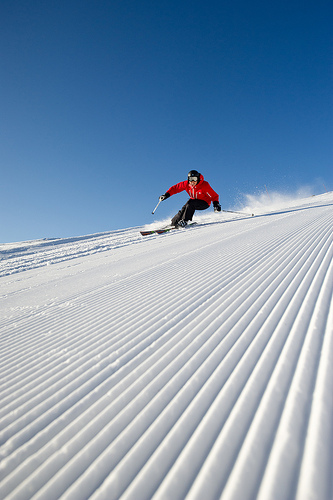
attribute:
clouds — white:
[235, 46, 293, 81]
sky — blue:
[2, 3, 329, 167]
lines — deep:
[2, 248, 317, 496]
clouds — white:
[11, 125, 93, 167]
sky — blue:
[3, 3, 332, 208]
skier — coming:
[159, 168, 221, 223]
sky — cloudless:
[155, 42, 292, 112]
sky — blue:
[4, 8, 321, 152]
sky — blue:
[86, 67, 137, 94]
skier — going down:
[156, 170, 223, 229]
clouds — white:
[47, 129, 91, 170]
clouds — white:
[12, 167, 45, 195]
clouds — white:
[75, 171, 109, 201]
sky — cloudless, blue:
[0, 2, 327, 246]